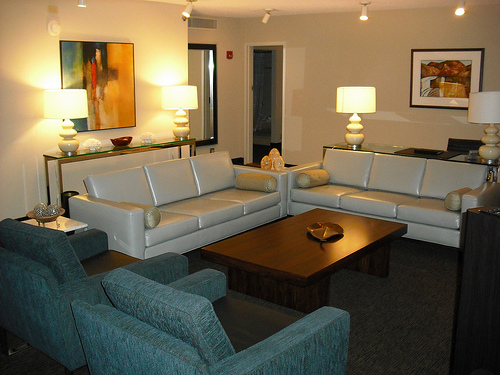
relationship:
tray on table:
[308, 220, 344, 243] [200, 207, 408, 312]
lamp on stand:
[160, 85, 198, 141] [42, 137, 197, 216]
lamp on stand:
[43, 87, 89, 157] [42, 137, 197, 216]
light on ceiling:
[453, 5, 465, 17] [109, 0, 488, 24]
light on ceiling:
[359, 11, 369, 21] [109, 0, 488, 24]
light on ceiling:
[262, 11, 270, 25] [109, 0, 488, 24]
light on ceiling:
[182, 3, 192, 18] [109, 0, 488, 24]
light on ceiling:
[75, 0, 87, 9] [109, 0, 488, 24]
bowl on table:
[110, 136, 132, 146] [39, 136, 201, 202]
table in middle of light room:
[200, 208, 408, 314] [0, 0, 500, 375]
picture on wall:
[59, 41, 137, 133] [4, 2, 186, 39]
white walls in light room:
[125, 16, 422, 168] [0, 0, 500, 375]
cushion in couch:
[134, 200, 198, 251] [62, 149, 289, 273]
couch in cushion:
[67, 150, 288, 261] [170, 200, 242, 217]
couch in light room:
[70, 152, 288, 262] [0, 0, 500, 375]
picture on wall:
[59, 33, 136, 134] [0, 0, 190, 217]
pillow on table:
[271, 150, 362, 192] [239, 136, 374, 223]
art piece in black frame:
[420, 60, 473, 98] [410, 48, 485, 110]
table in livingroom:
[200, 207, 408, 312] [2, 2, 497, 370]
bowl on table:
[89, 114, 164, 162] [44, 137, 192, 168]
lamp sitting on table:
[160, 69, 215, 144] [43, 136, 200, 215]